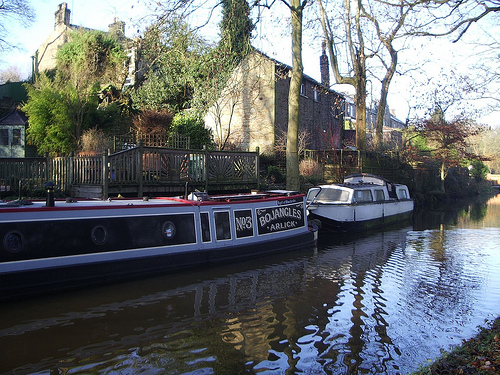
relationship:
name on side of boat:
[233, 207, 301, 232] [302, 169, 416, 229]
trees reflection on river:
[246, 10, 453, 142] [42, 225, 482, 373]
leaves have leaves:
[132, 37, 218, 106] [132, 37, 205, 111]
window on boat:
[348, 188, 375, 203] [302, 169, 416, 229]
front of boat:
[306, 194, 343, 231] [300, 171, 414, 233]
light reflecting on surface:
[300, 240, 441, 352] [21, 262, 478, 372]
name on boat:
[226, 202, 306, 235] [302, 154, 435, 251]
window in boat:
[353, 190, 374, 203] [296, 152, 431, 242]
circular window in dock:
[60, 213, 129, 250] [0, 146, 262, 192]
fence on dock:
[4, 146, 264, 196] [4, 189, 305, 209]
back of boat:
[387, 180, 419, 220] [305, 172, 419, 227]